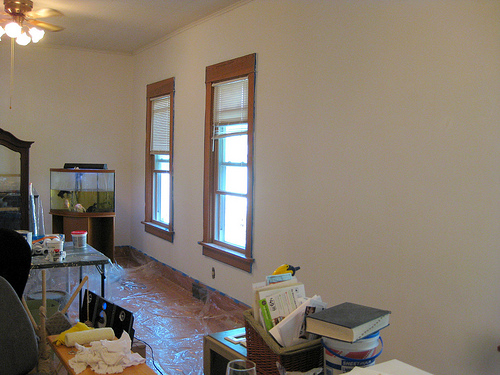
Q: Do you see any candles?
A: No, there are no candles.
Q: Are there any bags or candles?
A: No, there are no candles or bags.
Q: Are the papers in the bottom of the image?
A: Yes, the papers are in the bottom of the image.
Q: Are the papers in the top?
A: No, the papers are in the bottom of the image.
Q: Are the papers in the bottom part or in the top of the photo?
A: The papers are in the bottom of the image.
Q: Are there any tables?
A: Yes, there is a table.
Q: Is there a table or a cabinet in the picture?
A: Yes, there is a table.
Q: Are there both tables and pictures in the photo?
A: No, there is a table but no pictures.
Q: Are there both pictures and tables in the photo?
A: No, there is a table but no pictures.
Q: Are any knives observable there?
A: No, there are no knives.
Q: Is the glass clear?
A: Yes, the glass is clear.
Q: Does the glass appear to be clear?
A: Yes, the glass is clear.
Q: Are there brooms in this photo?
A: No, there are no brooms.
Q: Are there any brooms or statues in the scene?
A: No, there are no brooms or statues.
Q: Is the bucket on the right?
A: Yes, the bucket is on the right of the image.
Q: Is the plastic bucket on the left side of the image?
A: No, the bucket is on the right of the image.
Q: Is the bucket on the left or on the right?
A: The bucket is on the right of the image.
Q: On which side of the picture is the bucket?
A: The bucket is on the right of the image.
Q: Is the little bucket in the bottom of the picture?
A: Yes, the bucket is in the bottom of the image.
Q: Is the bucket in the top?
A: No, the bucket is in the bottom of the image.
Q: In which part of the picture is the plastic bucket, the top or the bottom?
A: The bucket is in the bottom of the image.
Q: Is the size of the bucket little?
A: Yes, the bucket is little.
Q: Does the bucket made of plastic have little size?
A: Yes, the bucket is little.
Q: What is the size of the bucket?
A: The bucket is little.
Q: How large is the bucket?
A: The bucket is little.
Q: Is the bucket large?
A: No, the bucket is little.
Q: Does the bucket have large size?
A: No, the bucket is little.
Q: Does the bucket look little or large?
A: The bucket is little.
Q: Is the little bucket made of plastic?
A: Yes, the bucket is made of plastic.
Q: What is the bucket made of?
A: The bucket is made of plastic.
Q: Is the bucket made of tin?
A: No, the bucket is made of plastic.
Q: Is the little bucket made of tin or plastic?
A: The bucket is made of plastic.